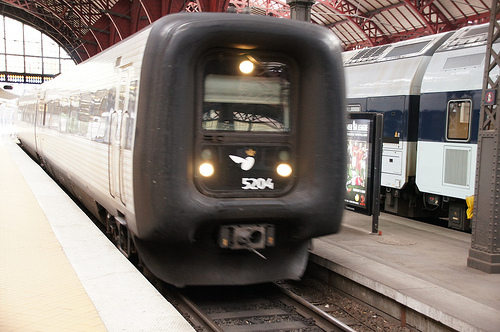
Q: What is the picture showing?
A: It is showing a station.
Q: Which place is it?
A: It is a station.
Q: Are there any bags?
A: No, there are no bags.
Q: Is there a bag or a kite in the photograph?
A: No, there are no bags or kites.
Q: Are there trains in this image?
A: Yes, there is a train.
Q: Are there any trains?
A: Yes, there is a train.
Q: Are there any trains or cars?
A: Yes, there is a train.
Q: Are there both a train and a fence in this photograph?
A: No, there is a train but no fences.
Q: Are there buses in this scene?
A: No, there are no buses.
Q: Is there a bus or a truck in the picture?
A: No, there are no buses or trucks.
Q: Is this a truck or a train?
A: This is a train.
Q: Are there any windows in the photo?
A: Yes, there is a window.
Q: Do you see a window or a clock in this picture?
A: Yes, there is a window.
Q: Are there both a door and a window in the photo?
A: Yes, there are both a window and a door.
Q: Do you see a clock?
A: No, there are no clocks.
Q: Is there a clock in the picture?
A: No, there are no clocks.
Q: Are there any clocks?
A: No, there are no clocks.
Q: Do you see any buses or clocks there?
A: No, there are no clocks or buses.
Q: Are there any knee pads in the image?
A: No, there are no knee pads.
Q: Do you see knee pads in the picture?
A: No, there are no knee pads.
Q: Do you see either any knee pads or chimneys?
A: No, there are no knee pads or chimneys.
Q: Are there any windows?
A: Yes, there is a window.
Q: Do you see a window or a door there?
A: Yes, there is a window.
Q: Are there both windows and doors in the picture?
A: Yes, there are both a window and a door.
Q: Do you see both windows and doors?
A: Yes, there are both a window and a door.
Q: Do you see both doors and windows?
A: Yes, there are both a window and a door.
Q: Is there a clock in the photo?
A: No, there are no clocks.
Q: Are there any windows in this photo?
A: Yes, there is a window.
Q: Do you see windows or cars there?
A: Yes, there is a window.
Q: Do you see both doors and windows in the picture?
A: Yes, there are both a window and a door.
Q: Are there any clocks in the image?
A: No, there are no clocks.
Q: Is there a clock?
A: No, there are no clocks.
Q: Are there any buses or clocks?
A: No, there are no clocks or buses.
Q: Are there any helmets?
A: No, there are no helmets.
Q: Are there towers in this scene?
A: No, there are no towers.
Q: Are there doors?
A: Yes, there is a door.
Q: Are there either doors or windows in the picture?
A: Yes, there is a door.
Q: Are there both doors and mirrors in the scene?
A: No, there is a door but no mirrors.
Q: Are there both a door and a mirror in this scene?
A: No, there is a door but no mirrors.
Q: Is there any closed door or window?
A: Yes, there is a closed door.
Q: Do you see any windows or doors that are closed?
A: Yes, the door is closed.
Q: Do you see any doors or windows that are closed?
A: Yes, the door is closed.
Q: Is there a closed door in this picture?
A: Yes, there is a closed door.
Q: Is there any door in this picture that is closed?
A: Yes, there is a door that is closed.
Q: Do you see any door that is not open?
A: Yes, there is an closed door.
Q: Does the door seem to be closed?
A: Yes, the door is closed.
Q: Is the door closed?
A: Yes, the door is closed.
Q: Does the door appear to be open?
A: No, the door is closed.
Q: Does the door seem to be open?
A: No, the door is closed.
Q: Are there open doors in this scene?
A: No, there is a door but it is closed.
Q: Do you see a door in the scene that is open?
A: No, there is a door but it is closed.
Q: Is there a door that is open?
A: No, there is a door but it is closed.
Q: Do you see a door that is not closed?
A: No, there is a door but it is closed.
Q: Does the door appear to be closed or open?
A: The door is closed.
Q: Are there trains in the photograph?
A: Yes, there is a train.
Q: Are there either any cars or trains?
A: Yes, there is a train.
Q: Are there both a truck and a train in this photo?
A: No, there is a train but no trucks.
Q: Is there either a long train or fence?
A: Yes, there is a long train.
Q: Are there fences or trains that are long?
A: Yes, the train is long.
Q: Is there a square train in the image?
A: Yes, there is a square train.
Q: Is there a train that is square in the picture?
A: Yes, there is a square train.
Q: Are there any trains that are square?
A: Yes, there is a train that is square.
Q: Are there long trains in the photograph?
A: Yes, there is a long train.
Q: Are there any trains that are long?
A: Yes, there is a train that is long.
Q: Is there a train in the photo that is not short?
A: Yes, there is a long train.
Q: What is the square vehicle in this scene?
A: The vehicle is a train.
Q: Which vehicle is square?
A: The vehicle is a train.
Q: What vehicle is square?
A: The vehicle is a train.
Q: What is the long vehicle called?
A: The vehicle is a train.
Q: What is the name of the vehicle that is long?
A: The vehicle is a train.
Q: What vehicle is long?
A: The vehicle is a train.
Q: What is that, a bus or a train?
A: That is a train.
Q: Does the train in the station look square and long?
A: Yes, the train is square and long.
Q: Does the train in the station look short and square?
A: No, the train is square but long.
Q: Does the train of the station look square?
A: Yes, the train is square.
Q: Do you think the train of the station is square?
A: Yes, the train is square.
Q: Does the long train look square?
A: Yes, the train is square.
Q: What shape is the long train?
A: The train is square.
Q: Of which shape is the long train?
A: The train is square.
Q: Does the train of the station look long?
A: Yes, the train is long.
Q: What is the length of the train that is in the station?
A: The train is long.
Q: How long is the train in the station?
A: The train is long.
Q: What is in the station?
A: The train is in the station.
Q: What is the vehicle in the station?
A: The vehicle is a train.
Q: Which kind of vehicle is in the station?
A: The vehicle is a train.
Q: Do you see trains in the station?
A: Yes, there is a train in the station.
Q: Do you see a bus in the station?
A: No, there is a train in the station.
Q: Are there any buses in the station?
A: No, there is a train in the station.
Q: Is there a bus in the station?
A: No, there is a train in the station.